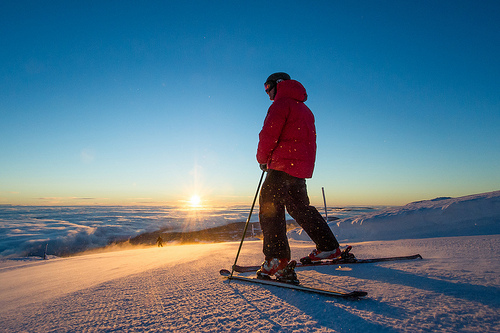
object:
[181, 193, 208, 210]
sun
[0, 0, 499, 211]
sky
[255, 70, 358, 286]
man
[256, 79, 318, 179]
jacket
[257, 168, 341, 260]
pants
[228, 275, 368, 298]
skis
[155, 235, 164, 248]
person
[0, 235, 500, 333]
snow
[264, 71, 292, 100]
helmet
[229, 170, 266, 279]
poles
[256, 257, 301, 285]
boots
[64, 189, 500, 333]
mountain